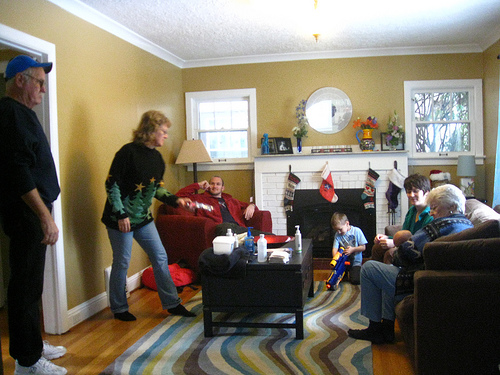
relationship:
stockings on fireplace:
[279, 164, 406, 217] [248, 140, 409, 269]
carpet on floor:
[93, 247, 374, 374] [3, 267, 417, 375]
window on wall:
[404, 78, 482, 166] [183, 49, 487, 263]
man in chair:
[177, 172, 277, 238] [155, 187, 273, 292]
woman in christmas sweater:
[102, 107, 198, 321] [102, 138, 178, 232]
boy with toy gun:
[323, 208, 365, 289] [324, 246, 354, 291]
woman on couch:
[346, 183, 473, 344] [382, 190, 499, 374]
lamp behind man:
[174, 135, 213, 190] [177, 172, 277, 238]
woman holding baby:
[347, 183, 473, 349] [389, 225, 417, 251]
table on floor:
[201, 226, 316, 341] [3, 267, 417, 375]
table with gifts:
[201, 226, 316, 341] [210, 222, 306, 264]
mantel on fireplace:
[252, 133, 409, 161] [248, 140, 409, 269]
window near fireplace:
[178, 84, 262, 173] [248, 140, 409, 269]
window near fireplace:
[395, 76, 486, 168] [248, 140, 409, 269]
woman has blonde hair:
[347, 183, 473, 349] [423, 184, 468, 216]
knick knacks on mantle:
[253, 99, 409, 153] [259, 141, 411, 156]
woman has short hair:
[375, 169, 436, 262] [397, 172, 432, 197]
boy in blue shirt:
[323, 208, 365, 289] [331, 227, 369, 266]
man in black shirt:
[1, 51, 81, 375] [0, 92, 62, 207]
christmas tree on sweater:
[104, 177, 169, 223] [102, 138, 178, 232]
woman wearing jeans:
[102, 107, 198, 321] [99, 217, 188, 314]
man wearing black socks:
[1, 51, 81, 375] [5, 344, 43, 368]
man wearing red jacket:
[177, 172, 277, 238] [175, 179, 254, 230]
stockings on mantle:
[279, 164, 406, 217] [259, 141, 411, 156]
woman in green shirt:
[375, 169, 436, 262] [387, 201, 433, 243]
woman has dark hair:
[375, 169, 436, 262] [397, 172, 432, 197]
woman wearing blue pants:
[102, 107, 198, 321] [99, 217, 188, 314]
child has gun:
[323, 208, 365, 289] [324, 246, 354, 291]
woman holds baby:
[347, 183, 473, 349] [389, 225, 417, 251]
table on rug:
[201, 226, 316, 341] [93, 247, 374, 374]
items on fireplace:
[254, 95, 412, 213] [248, 140, 409, 269]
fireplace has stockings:
[248, 140, 409, 269] [279, 164, 406, 217]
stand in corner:
[420, 168, 492, 211] [440, 47, 500, 200]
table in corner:
[420, 168, 492, 211] [440, 47, 500, 200]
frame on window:
[391, 71, 489, 162] [395, 76, 486, 168]